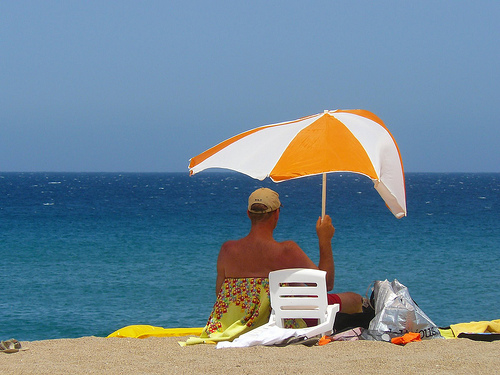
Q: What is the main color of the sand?
A: Tan.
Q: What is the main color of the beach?
A: Brown.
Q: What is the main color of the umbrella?
A: Orange.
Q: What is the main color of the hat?
A: White.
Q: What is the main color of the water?
A: Blue.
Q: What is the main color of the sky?
A: Blue.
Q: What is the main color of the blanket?
A: Yellow.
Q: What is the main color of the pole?
A: White.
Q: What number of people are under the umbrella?
A: One.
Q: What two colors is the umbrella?
A: White and orange.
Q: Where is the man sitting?
A: On the beach.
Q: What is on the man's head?
A: A hat.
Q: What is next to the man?
A: A chair.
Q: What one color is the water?
A: Blue.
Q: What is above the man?
A: An umbrella.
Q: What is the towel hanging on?
A: A chair.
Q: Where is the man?
A: On the beach .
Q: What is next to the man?
A: White chair.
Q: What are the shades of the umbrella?
A: Orange an white.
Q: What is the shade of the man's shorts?
A: Red.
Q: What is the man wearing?
A: A hat.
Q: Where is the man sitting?
A: Under the umbrella.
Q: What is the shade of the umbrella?
A: Yellow and white.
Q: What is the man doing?
A: Sitting on the beach.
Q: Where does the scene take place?
A: At the beach.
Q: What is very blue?
A: Ocean.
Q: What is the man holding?
A: Umbrella.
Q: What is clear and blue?
A: Sky.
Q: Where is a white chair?
A: Behind the man.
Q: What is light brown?
A: Sand.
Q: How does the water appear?
A: Calm.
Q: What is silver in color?
A: Bag.